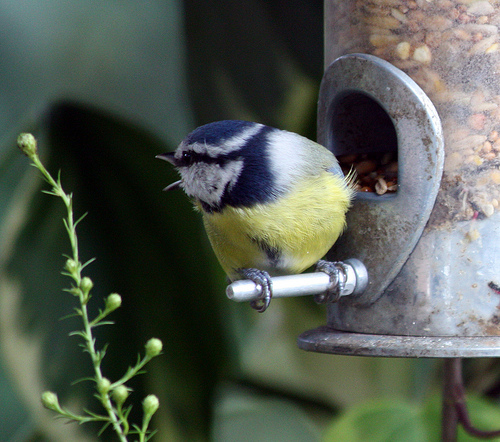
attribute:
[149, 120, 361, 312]
bird — facing to left, perched, small, black, yellow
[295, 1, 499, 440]
feeder — full, made of metal, open, clear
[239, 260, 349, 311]
feet — black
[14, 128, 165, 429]
plant — green, tall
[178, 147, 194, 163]
eye — black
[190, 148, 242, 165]
line — black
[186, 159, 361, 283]
part of bird — yellow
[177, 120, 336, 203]
half of body — gray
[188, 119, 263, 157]
stripe — white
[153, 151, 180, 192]
beak — open, opened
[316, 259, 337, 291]
nail — black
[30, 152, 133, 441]
stem — brown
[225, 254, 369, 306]
road — silver, small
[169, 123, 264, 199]
head — gray